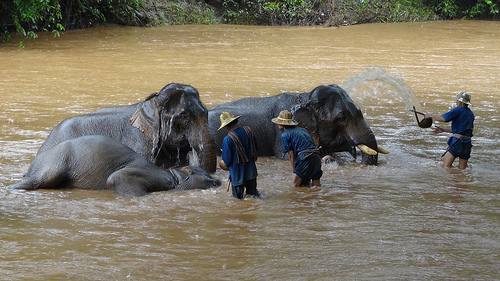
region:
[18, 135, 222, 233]
elephant laying in river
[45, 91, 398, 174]
elephants sitting in river water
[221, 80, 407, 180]
elephant with tusks in water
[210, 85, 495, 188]
people wearing straw hats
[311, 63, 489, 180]
person throwing water on elephant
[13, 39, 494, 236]
muddy water in river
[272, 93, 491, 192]
men wearing high rubber boots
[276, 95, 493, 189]
men wearing blue short sleeved shirts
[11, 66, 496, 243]
elephants being bathed in river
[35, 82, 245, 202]
elephant with water streaming down side of face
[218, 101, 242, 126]
His hat is tan.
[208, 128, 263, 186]
His shirt is blue.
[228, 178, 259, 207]
The pants are black.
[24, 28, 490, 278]
The water is muddy.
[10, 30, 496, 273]
The water is calm.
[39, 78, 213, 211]
The elephants are wet.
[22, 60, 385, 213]
The elephants are in the water.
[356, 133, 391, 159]
His tusks are white.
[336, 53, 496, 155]
He is splashing the elephants.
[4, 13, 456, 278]
The water is shallow.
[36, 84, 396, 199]
elephants in a river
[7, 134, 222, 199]
an elephant laying down in a river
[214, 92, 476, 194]
three men in a river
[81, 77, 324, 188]
two men in front of elephants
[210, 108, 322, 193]
two men wearing a hat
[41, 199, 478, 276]
ripples in brown river water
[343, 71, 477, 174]
a man tossing water on an elephant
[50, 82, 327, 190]
an elephant and a man looking at each other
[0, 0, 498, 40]
trees and shurbs on the river bank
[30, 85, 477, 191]
three elephants and three men in a river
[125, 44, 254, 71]
brown waters in the lake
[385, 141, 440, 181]
small waves in the water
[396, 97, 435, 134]
water holder in man's hand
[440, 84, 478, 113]
cap on man's head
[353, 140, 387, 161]
brown tusk on elephant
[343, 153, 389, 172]
elephant's trunk in the water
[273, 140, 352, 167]
sash around man's waist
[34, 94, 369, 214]
elephants in the water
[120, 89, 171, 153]
black floppy ear on elephant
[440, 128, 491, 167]
man wearing blue shorts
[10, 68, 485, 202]
Three men bathing two elephants in the water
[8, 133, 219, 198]
the elephant on the left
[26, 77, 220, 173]
The elephant in the middle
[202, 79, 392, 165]
The elephant on the right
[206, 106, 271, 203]
The man on the right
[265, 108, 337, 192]
The man in the middle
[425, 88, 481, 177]
The man on the right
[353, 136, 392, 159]
Tusks on the elephant on the right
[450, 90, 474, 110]
The man on the right's hat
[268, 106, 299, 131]
the man in the middle's hat